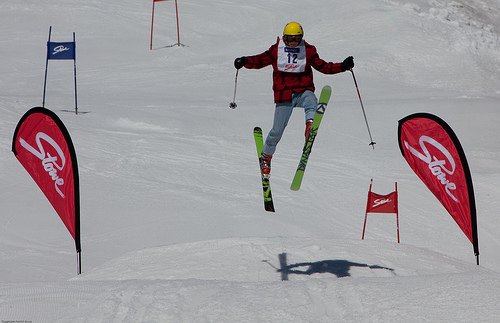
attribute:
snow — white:
[127, 139, 215, 236]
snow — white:
[102, 192, 234, 292]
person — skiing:
[224, 23, 364, 214]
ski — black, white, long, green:
[237, 105, 298, 233]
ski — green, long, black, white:
[287, 69, 322, 210]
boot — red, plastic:
[257, 151, 277, 177]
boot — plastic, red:
[290, 114, 332, 155]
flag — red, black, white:
[16, 98, 109, 284]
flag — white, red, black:
[387, 95, 484, 260]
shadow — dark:
[256, 244, 429, 287]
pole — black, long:
[223, 59, 253, 113]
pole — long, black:
[349, 57, 389, 177]